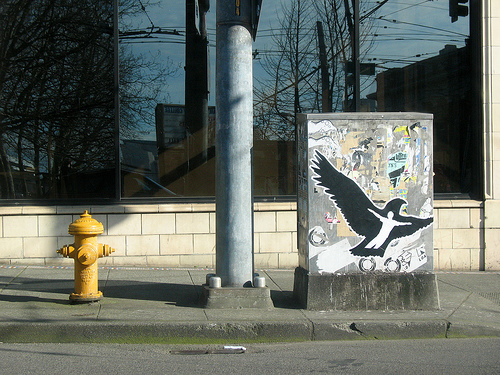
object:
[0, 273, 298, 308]
shadow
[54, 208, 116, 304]
fire hydrant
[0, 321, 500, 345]
curb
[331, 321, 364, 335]
crack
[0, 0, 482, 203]
reflection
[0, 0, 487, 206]
window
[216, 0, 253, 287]
pole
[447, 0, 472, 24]
light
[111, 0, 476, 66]
wires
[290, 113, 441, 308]
metal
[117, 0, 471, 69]
power lines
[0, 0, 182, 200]
tree reflection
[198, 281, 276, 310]
concrete base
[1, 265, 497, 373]
sidewalk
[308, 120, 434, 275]
graffiti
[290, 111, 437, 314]
pillar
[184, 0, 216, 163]
reflection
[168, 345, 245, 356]
gutter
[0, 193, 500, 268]
wall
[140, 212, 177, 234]
tile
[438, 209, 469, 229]
tile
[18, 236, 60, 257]
tile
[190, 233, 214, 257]
tile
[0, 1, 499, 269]
building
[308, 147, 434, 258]
bird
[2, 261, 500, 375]
concrete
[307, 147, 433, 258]
sticker